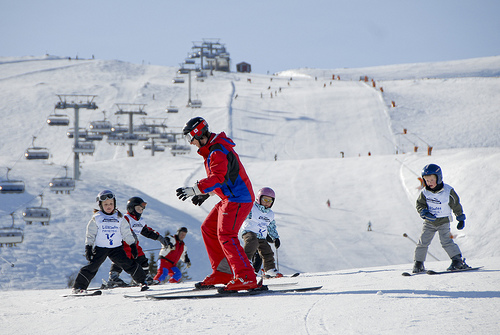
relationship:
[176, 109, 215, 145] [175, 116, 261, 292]
helmet on instructor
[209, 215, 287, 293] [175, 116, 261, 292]
pants on instructor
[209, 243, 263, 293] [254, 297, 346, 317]
boot in snow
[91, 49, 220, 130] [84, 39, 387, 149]
lift on mountain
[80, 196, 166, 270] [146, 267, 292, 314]
kids on skis